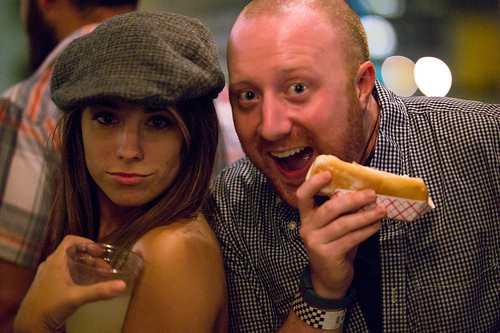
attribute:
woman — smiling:
[0, 5, 237, 328]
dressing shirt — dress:
[201, 88, 484, 331]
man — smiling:
[203, 0, 472, 329]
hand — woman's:
[12, 231, 127, 327]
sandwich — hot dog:
[288, 155, 446, 218]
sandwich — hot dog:
[296, 150, 436, 231]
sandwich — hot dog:
[293, 150, 445, 213]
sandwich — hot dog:
[298, 152, 428, 227]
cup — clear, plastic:
[55, 237, 149, 327]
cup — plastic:
[54, 238, 143, 329]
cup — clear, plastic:
[60, 230, 151, 327]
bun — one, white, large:
[310, 152, 449, 220]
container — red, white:
[327, 185, 425, 230]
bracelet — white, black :
[283, 282, 348, 329]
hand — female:
[26, 236, 130, 329]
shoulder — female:
[132, 211, 224, 317]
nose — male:
[258, 92, 283, 143]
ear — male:
[357, 54, 376, 113]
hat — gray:
[56, 40, 225, 100]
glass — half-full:
[69, 240, 137, 329]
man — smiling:
[230, 16, 364, 185]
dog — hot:
[293, 144, 432, 220]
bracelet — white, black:
[283, 280, 353, 331]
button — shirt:
[275, 212, 296, 241]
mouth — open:
[266, 132, 306, 178]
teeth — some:
[261, 139, 311, 176]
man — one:
[8, 1, 162, 277]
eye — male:
[230, 80, 258, 110]